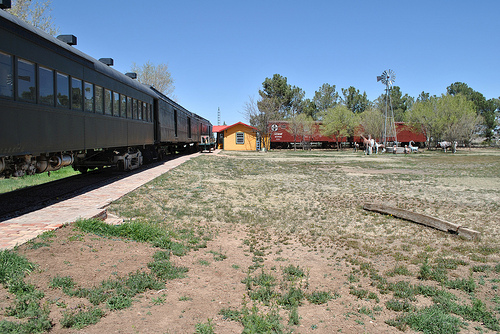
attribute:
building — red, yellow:
[209, 116, 269, 159]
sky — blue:
[5, 0, 498, 122]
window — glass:
[125, 97, 138, 120]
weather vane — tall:
[374, 67, 400, 154]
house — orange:
[212, 120, 270, 151]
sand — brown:
[1, 139, 498, 332]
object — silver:
[360, 197, 485, 243]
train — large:
[0, 6, 217, 184]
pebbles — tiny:
[340, 294, 391, 332]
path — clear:
[0, 151, 202, 257]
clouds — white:
[88, 7, 265, 96]